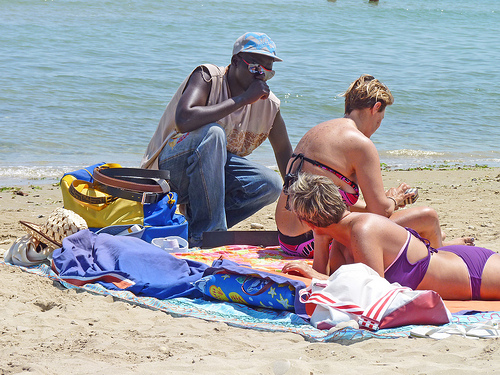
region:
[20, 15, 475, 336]
people close to each other on the beach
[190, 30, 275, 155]
person with hand in front of mouth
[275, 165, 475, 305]
head turned toward person in cap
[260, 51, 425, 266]
woman in printed bikini holding object in hands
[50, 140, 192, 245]
belts on top of yellow and blue bag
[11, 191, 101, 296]
straw hat on corner of blanket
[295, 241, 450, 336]
red and white bag in front of sunbather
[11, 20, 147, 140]
calm aquamarine-colored water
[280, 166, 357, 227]
woman with short frosted hair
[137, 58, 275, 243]
person wearing sleeveless shirt and jeans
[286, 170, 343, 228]
Short hair of a woman laying on a beach with purple swimsuit on.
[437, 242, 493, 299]
Purple bikini bottom on woman lying down.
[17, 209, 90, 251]
Tan and brown hat laying on a blanket.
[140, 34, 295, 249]
A colored man kneeling down near a woman.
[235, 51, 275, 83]
Red framed sunglasses on the face of a colored man.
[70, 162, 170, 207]
Loose belts laying on top of a blue and yellow bag.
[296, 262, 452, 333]
A red and white beach bag laying on a beach blanket.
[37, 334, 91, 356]
Sand on the beach.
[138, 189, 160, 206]
Silver buckle on the front of a black belt.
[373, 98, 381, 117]
Right ear on the right side of a sitting woman's head.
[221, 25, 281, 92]
Man wearing reflective sunglasses.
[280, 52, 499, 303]
Two women wearing bikinis.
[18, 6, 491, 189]
Ocean water in the background.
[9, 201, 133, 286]
Woman's straw hat sitting on the blanket.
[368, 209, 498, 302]
Woman's purple bikini.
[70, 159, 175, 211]
Several black and brown belts sitting on a bag.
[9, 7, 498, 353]
People hanging out at the beach.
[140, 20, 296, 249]
Man wearing blue jeans and a brown tank top.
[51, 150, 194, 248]
Yellow and blue duffel bag sitting in the sand.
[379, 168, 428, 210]
Woman holding a striped box.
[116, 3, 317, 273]
man crouching on the beach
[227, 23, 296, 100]
man wearing cap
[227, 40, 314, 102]
man wearing red sun glasses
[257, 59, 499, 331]
ladies on the beach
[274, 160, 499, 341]
lady wearing purple bikini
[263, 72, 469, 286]
lady wearing pink and black bikini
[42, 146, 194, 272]
blue and yellow bag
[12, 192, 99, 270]
grass brown and cream hat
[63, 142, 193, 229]
belts on bag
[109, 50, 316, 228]
man wearing brown shirt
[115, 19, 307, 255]
man kneeling on beach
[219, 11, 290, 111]
man wearing grey and blue cap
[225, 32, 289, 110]
man wearing red sunglasses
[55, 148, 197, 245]
belts on top of bag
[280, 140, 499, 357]
lady laying on beach towel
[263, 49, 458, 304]
lady sitting on beach towel on the beach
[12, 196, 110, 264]
hat on the towels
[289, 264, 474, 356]
red and white bag on towel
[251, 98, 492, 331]
ladies wearing bikinis